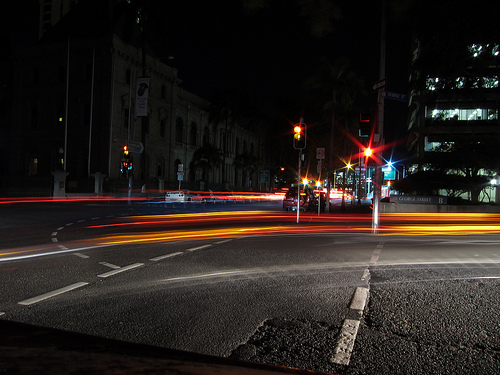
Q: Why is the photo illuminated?
A: Light fixtures.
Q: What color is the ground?
A: Gray.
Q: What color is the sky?
A: Black.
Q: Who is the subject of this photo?
A: The street.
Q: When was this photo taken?
A: During the night.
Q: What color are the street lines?
A: White.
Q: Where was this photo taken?
A: In a street.